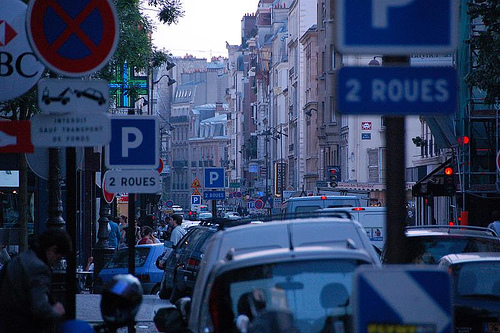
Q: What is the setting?
A: A busy street.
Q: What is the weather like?
A: Clear.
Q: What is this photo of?
A: Traffic.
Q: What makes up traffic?
A: Cars.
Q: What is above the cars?
A: Signs.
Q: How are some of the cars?
A: Parked.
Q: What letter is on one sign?
A: P.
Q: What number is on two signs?
A: 2.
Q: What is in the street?
A: Cars.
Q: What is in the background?
A: Buildings.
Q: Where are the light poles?
A: Sidewalk.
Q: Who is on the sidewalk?
A: A man.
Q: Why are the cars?
A: On the street.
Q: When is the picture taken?
A: Daytime.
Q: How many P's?
A: 4.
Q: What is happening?
A: Traffic jam.